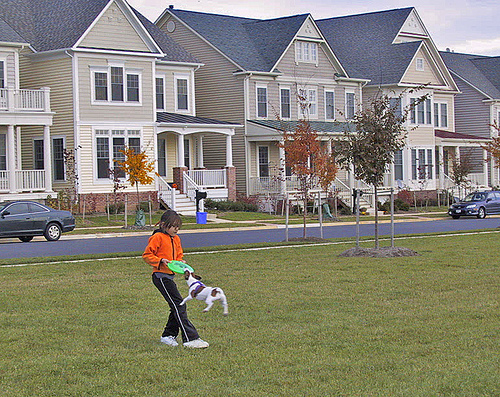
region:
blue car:
[444, 183, 499, 221]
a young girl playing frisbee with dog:
[137, 204, 237, 361]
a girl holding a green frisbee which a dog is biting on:
[130, 211, 248, 360]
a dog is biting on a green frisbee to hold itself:
[159, 255, 244, 318]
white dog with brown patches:
[175, 264, 245, 322]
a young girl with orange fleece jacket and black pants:
[144, 206, 241, 366]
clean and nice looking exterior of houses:
[252, 0, 497, 233]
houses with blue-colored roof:
[225, 0, 488, 219]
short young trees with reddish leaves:
[269, 60, 442, 275]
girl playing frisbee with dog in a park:
[54, 101, 499, 356]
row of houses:
[1, 0, 486, 210]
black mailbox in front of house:
[125, 132, 207, 218]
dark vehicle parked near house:
[0, 135, 80, 238]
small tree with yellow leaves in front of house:
[106, 88, 156, 229]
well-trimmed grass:
[241, 273, 487, 385]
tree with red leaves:
[266, 90, 336, 250]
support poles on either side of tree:
[340, 123, 416, 259]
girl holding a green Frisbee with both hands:
[143, 202, 185, 337]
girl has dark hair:
[150, 203, 180, 246]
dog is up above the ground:
[138, 205, 238, 365]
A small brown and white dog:
[185, 265, 228, 323]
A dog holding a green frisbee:
[165, 251, 235, 315]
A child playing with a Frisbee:
[134, 205, 211, 361]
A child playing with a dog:
[139, 204, 229, 372]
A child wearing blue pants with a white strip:
[145, 206, 209, 356]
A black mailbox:
[191, 181, 209, 207]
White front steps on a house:
[154, 172, 213, 212]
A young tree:
[349, 98, 402, 258]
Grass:
[287, 311, 414, 370]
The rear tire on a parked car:
[42, 218, 63, 244]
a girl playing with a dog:
[141, 207, 229, 349]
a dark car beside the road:
[0, 197, 82, 239]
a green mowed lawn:
[328, 247, 495, 389]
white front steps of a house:
[168, 188, 203, 214]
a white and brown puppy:
[181, 267, 245, 314]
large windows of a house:
[99, 129, 144, 181]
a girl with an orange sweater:
[131, 209, 245, 274]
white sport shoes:
[158, 330, 213, 350]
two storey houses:
[3, 2, 478, 204]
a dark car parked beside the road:
[451, 186, 498, 218]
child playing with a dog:
[144, 208, 229, 352]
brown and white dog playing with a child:
[177, 265, 229, 314]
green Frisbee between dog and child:
[168, 255, 190, 272]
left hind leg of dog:
[203, 294, 214, 311]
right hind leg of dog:
[220, 291, 235, 313]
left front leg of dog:
[178, 292, 193, 305]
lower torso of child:
[149, 273, 205, 350]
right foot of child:
[186, 336, 209, 346]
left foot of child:
[158, 330, 176, 347]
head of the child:
[158, 208, 181, 233]